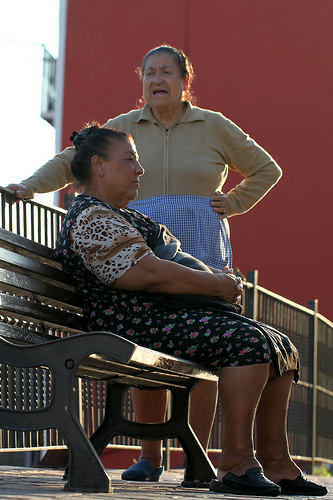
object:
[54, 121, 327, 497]
women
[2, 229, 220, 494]
bench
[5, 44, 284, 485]
woman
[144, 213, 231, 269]
apron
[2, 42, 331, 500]
bus stop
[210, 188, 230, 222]
hand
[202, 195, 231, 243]
hip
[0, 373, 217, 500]
legs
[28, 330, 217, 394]
seat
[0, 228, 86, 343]
back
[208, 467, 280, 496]
shoes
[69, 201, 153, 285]
shirt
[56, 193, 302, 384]
dress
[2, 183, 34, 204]
hand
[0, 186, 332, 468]
fence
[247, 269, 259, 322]
post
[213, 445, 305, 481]
ankles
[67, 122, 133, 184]
hair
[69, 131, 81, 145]
clip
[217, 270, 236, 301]
hands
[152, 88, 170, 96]
mouth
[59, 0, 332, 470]
wall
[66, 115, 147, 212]
top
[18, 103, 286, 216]
dress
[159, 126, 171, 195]
zipper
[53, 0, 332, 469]
building